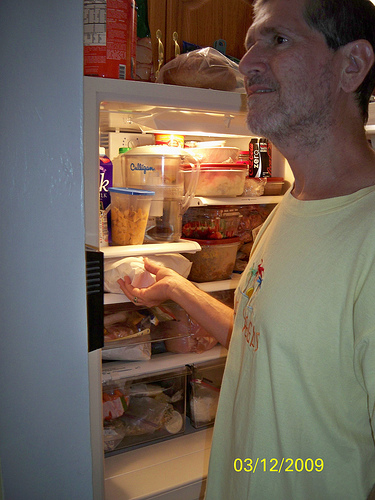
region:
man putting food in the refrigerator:
[116, 0, 373, 498]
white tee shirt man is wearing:
[204, 180, 373, 498]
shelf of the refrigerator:
[100, 344, 240, 382]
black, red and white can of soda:
[248, 132, 269, 179]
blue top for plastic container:
[107, 183, 156, 196]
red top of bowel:
[191, 235, 242, 247]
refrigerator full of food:
[80, 76, 288, 460]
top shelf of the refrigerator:
[182, 194, 287, 206]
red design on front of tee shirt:
[240, 314, 261, 349]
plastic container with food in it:
[109, 191, 149, 244]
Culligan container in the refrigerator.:
[107, 129, 208, 270]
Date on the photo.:
[202, 430, 373, 490]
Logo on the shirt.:
[233, 259, 292, 341]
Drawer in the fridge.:
[119, 359, 199, 445]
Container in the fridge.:
[182, 148, 265, 210]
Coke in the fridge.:
[231, 127, 284, 190]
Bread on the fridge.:
[145, 30, 247, 101]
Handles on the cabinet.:
[146, 17, 214, 67]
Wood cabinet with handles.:
[141, 3, 261, 98]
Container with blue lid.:
[106, 177, 146, 237]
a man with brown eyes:
[121, 1, 370, 498]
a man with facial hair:
[113, 6, 372, 498]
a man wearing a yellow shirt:
[113, 4, 374, 492]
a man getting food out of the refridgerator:
[106, 3, 372, 498]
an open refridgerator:
[83, 83, 303, 471]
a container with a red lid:
[192, 237, 242, 277]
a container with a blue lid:
[110, 185, 152, 246]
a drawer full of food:
[98, 363, 214, 451]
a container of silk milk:
[95, 147, 119, 246]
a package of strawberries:
[187, 206, 240, 241]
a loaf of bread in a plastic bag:
[156, 45, 237, 90]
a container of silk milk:
[98, 145, 111, 228]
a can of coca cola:
[247, 137, 271, 183]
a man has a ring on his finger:
[132, 294, 138, 303]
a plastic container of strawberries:
[183, 206, 239, 239]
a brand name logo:
[128, 160, 155, 174]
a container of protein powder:
[81, 0, 138, 80]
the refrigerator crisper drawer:
[101, 364, 189, 458]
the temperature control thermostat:
[127, 136, 140, 147]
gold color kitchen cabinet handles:
[155, 26, 165, 76]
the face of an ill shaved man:
[234, 50, 373, 161]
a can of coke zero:
[249, 136, 269, 179]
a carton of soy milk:
[96, 144, 114, 246]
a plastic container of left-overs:
[109, 186, 156, 246]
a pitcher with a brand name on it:
[120, 145, 199, 241]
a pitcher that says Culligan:
[118, 145, 198, 241]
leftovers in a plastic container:
[180, 162, 249, 196]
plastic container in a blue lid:
[110, 185, 155, 245]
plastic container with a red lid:
[184, 233, 239, 280]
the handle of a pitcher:
[180, 155, 199, 211]